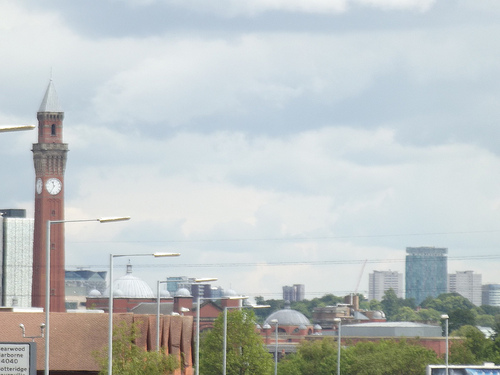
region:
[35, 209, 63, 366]
Tall metal light post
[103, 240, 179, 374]
Tall metal light post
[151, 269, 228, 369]
Tall metal light post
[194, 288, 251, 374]
Tall metal light post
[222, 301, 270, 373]
Tall metal light post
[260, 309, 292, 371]
Tall metal light post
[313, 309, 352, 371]
Tall metal light post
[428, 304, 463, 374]
Tall metal light post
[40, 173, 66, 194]
Black and white clock on the tower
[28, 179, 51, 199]
Black and white clock on the tower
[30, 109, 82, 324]
tall clock tower on left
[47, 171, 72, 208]
white face on clock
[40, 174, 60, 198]
black hands on clock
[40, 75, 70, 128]
white and pointed roof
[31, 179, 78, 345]
tower is red brick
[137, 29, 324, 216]
sky is grey and cloudy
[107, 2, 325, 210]
heavy and puffy clouds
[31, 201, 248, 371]
grey and white light poles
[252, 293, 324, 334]
domed and grey building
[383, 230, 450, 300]
black tall building on right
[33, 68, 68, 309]
a tall brick clock tower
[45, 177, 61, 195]
a circular white clock face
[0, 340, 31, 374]
a sign with black text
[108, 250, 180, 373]
a white street lamp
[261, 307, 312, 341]
a brick building with a dome roof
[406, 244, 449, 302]
a tall glass building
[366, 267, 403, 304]
a very tall white building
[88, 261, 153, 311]
a building with a white dome roof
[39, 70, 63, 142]
a building's tall tower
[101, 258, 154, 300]
a white dome